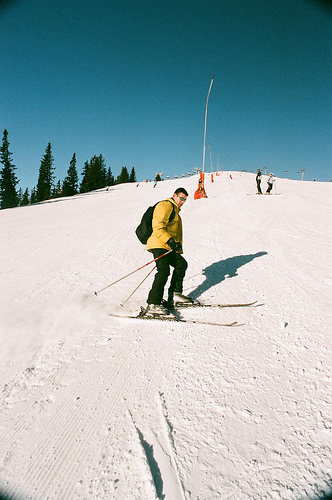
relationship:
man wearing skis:
[143, 184, 193, 314] [111, 297, 261, 330]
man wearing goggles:
[143, 184, 193, 314] [176, 192, 190, 204]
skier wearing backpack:
[143, 184, 193, 314] [136, 203, 155, 244]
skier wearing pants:
[143, 184, 193, 314] [146, 247, 187, 305]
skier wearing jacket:
[143, 184, 193, 314] [148, 198, 184, 254]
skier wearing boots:
[143, 184, 193, 314] [143, 290, 195, 322]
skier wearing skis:
[143, 184, 193, 314] [111, 297, 261, 330]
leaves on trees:
[1, 127, 165, 209] [1, 123, 165, 211]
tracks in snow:
[3, 336, 207, 499] [0, 168, 330, 499]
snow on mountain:
[0, 168, 330, 499] [2, 127, 329, 499]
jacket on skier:
[148, 198, 184, 254] [143, 184, 193, 314]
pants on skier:
[146, 247, 187, 305] [143, 184, 193, 314]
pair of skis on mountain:
[111, 297, 261, 330] [2, 127, 329, 499]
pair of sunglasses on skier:
[176, 192, 190, 204] [143, 184, 193, 314]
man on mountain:
[143, 184, 193, 314] [2, 127, 329, 499]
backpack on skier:
[136, 203, 155, 244] [143, 184, 193, 314]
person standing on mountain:
[256, 167, 266, 197] [2, 127, 329, 499]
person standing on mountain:
[265, 173, 280, 196] [2, 127, 329, 499]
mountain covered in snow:
[2, 127, 329, 499] [0, 168, 330, 499]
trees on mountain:
[1, 123, 165, 211] [2, 127, 329, 499]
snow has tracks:
[0, 168, 330, 499] [3, 336, 207, 499]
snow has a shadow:
[0, 168, 330, 499] [188, 244, 271, 302]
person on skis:
[256, 167, 266, 197] [254, 188, 267, 198]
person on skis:
[265, 173, 280, 196] [265, 190, 284, 198]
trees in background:
[1, 123, 165, 211] [1, 127, 330, 211]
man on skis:
[143, 184, 193, 314] [111, 297, 261, 330]